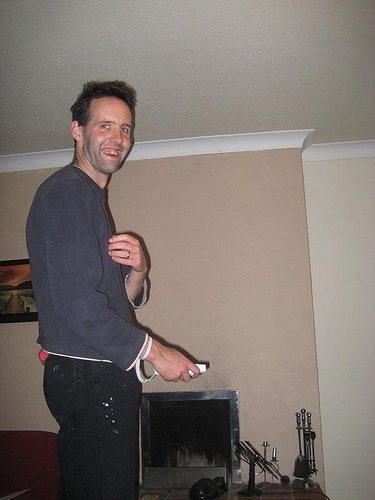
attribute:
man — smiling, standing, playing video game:
[24, 77, 202, 499]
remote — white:
[150, 362, 209, 380]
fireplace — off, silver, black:
[135, 388, 244, 491]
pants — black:
[41, 353, 142, 499]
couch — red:
[0, 430, 63, 500]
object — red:
[37, 346, 51, 364]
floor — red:
[136, 483, 328, 498]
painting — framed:
[1, 258, 38, 322]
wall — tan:
[4, 112, 327, 488]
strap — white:
[134, 331, 156, 386]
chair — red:
[2, 432, 351, 498]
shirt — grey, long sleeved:
[25, 162, 151, 374]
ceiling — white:
[2, 1, 374, 159]